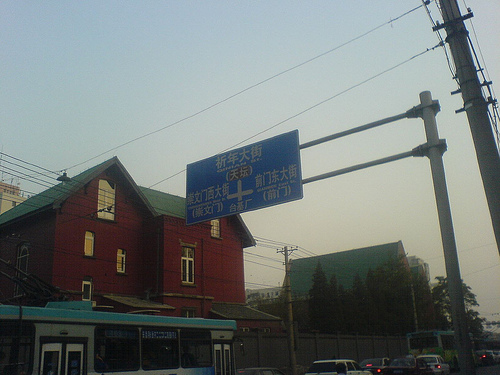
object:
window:
[186, 247, 195, 258]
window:
[115, 253, 126, 273]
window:
[211, 219, 221, 239]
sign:
[141, 330, 178, 340]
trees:
[305, 256, 345, 336]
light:
[366, 364, 371, 366]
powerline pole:
[429, 0, 499, 255]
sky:
[0, 0, 500, 336]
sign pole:
[301, 143, 426, 186]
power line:
[0, 41, 449, 244]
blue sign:
[187, 129, 303, 226]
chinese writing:
[183, 144, 300, 218]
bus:
[0, 301, 239, 375]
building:
[0, 156, 283, 333]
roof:
[283, 238, 399, 301]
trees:
[430, 275, 486, 335]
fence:
[0, 328, 409, 375]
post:
[417, 90, 476, 375]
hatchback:
[414, 355, 449, 375]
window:
[97, 178, 117, 221]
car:
[305, 358, 377, 375]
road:
[451, 365, 499, 375]